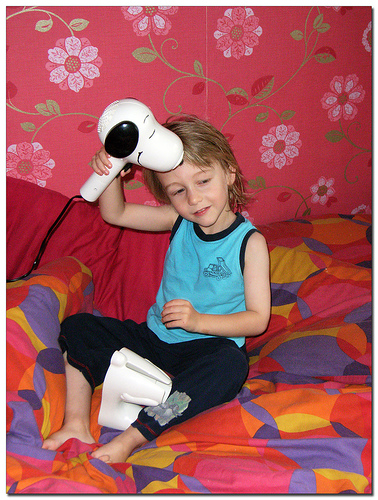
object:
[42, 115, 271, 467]
child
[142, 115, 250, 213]
hair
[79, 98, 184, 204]
blow dryer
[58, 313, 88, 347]
knee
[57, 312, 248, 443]
pyjamas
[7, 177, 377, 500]
bed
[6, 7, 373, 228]
wallpaper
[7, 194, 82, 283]
wire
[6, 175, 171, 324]
pillow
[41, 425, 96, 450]
foot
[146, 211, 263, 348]
shirt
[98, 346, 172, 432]
holder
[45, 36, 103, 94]
flower